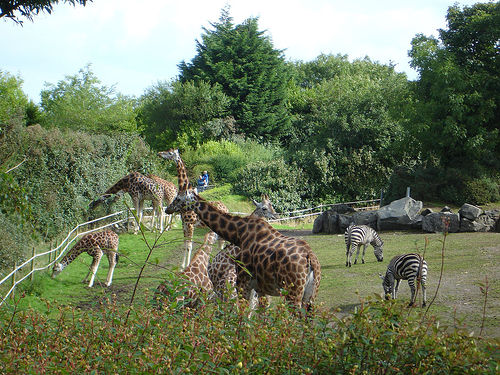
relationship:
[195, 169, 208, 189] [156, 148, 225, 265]
man behind giraffe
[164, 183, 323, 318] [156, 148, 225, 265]
giraffe in front of giraffe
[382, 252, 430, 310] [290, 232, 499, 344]
zebra eating grass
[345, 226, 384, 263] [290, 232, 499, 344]
zebra eating grass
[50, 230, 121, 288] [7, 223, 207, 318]
giraffe eating grass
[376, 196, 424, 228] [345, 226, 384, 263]
rock behind zebra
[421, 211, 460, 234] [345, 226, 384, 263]
rock behind zebra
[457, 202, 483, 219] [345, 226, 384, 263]
rock behind zebra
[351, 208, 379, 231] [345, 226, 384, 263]
rock behind zebra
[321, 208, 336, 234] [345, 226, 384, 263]
rock behind zebra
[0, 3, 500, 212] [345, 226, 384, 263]
trees behind zebra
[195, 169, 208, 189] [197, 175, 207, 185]
man wearing shirt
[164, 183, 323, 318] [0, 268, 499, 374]
giraffe standing in grass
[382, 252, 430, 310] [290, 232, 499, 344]
zebra standing in grass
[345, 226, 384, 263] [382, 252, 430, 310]
zebra behind zebra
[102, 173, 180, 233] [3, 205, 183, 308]
giraffe grazing beyond fence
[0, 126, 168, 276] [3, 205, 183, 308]
shrubs behind fence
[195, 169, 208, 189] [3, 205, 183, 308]
man behind fence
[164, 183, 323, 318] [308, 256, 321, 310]
giraffe has tail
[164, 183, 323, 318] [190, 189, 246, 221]
giraffe has mane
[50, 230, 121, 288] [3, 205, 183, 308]
giraffe inside fence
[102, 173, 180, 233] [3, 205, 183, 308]
giraffe inside fence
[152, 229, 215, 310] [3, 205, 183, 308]
giraffe inside fence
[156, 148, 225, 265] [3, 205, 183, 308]
giraffe inside fence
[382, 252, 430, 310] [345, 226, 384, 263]
zebra in front of zebra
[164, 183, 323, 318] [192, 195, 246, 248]
giraffe has neck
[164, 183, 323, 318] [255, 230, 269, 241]
giraffe has spot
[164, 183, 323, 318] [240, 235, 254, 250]
giraffe has spot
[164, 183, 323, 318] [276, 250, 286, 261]
giraffe has spot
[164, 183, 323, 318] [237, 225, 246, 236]
giraffe has spot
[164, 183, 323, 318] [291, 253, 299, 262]
giraffe has spot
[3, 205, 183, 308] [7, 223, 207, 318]
fence near grass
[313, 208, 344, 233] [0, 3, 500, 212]
rock near trees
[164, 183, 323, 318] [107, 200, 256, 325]
giraffe eating off tree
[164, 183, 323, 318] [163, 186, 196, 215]
giraffe has face